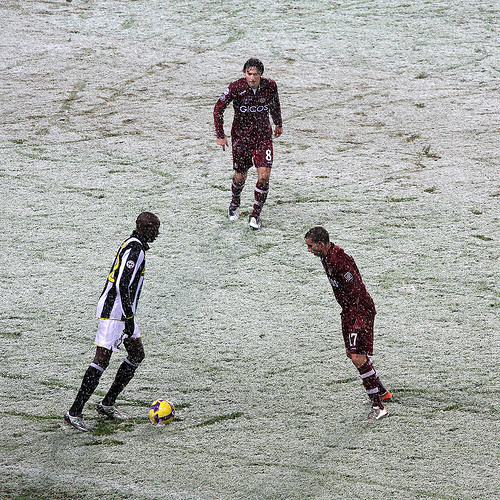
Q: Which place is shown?
A: It is a field.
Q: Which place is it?
A: It is a field.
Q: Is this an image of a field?
A: Yes, it is showing a field.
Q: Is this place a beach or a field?
A: It is a field.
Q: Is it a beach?
A: No, it is a field.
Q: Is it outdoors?
A: Yes, it is outdoors.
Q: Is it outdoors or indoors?
A: It is outdoors.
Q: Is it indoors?
A: No, it is outdoors.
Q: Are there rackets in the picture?
A: No, there are no rackets.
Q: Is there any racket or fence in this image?
A: No, there are no rackets or fences.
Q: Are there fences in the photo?
A: No, there are no fences.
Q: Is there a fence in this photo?
A: No, there are no fences.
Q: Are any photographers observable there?
A: No, there are no photographers.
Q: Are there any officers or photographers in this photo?
A: No, there are no photographers or officers.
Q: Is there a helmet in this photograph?
A: No, there are no helmets.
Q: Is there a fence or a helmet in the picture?
A: No, there are no helmets or fences.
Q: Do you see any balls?
A: Yes, there is a ball.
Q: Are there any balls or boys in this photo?
A: Yes, there is a ball.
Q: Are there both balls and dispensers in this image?
A: No, there is a ball but no dispensers.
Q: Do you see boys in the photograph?
A: No, there are no boys.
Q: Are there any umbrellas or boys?
A: No, there are no boys or umbrellas.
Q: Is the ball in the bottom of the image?
A: Yes, the ball is in the bottom of the image.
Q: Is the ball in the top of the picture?
A: No, the ball is in the bottom of the image.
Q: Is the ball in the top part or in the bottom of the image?
A: The ball is in the bottom of the image.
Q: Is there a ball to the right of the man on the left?
A: Yes, there is a ball to the right of the man.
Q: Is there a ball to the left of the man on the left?
A: No, the ball is to the right of the man.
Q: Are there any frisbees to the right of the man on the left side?
A: No, there is a ball to the right of the man.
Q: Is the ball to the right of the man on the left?
A: Yes, the ball is to the right of the man.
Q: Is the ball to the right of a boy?
A: No, the ball is to the right of the man.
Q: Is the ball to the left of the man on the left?
A: No, the ball is to the right of the man.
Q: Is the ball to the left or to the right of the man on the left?
A: The ball is to the right of the man.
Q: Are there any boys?
A: No, there are no boys.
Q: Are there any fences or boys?
A: No, there are no boys or fences.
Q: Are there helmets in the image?
A: No, there are no helmets.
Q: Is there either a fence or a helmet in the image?
A: No, there are no helmets or fences.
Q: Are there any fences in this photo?
A: No, there are no fences.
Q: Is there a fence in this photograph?
A: No, there are no fences.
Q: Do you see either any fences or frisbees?
A: No, there are no fences or frisbees.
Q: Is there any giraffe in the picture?
A: No, there are no giraffes.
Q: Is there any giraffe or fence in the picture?
A: No, there are no giraffes or fences.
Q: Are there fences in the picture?
A: No, there are no fences.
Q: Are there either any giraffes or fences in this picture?
A: No, there are no fences or giraffes.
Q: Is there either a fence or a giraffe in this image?
A: No, there are no fences or giraffes.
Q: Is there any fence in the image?
A: No, there are no fences.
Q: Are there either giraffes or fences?
A: No, there are no fences or giraffes.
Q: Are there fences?
A: No, there are no fences.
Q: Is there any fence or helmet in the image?
A: No, there are no fences or helmets.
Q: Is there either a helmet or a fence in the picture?
A: No, there are no fences or helmets.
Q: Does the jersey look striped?
A: Yes, the jersey is striped.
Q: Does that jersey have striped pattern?
A: Yes, the jersey is striped.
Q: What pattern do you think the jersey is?
A: The jersey is striped.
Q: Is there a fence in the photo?
A: No, there are no fences.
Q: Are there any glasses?
A: No, there are no glasses.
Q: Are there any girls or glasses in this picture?
A: No, there are no glasses or girls.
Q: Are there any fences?
A: No, there are no fences.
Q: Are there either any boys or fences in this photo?
A: No, there are no fences or boys.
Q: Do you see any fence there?
A: No, there are no fences.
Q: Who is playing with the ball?
A: The man is playing with the ball.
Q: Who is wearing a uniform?
A: The man is wearing a uniform.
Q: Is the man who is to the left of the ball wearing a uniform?
A: Yes, the man is wearing a uniform.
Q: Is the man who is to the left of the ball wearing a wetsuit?
A: No, the man is wearing a uniform.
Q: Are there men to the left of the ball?
A: Yes, there is a man to the left of the ball.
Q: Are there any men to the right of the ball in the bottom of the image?
A: No, the man is to the left of the ball.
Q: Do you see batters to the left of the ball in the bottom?
A: No, there is a man to the left of the ball.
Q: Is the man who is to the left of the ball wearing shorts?
A: Yes, the man is wearing shorts.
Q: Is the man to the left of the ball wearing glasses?
A: No, the man is wearing shorts.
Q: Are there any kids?
A: No, there are no kids.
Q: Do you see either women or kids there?
A: No, there are no kids or women.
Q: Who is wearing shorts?
A: The man is wearing shorts.